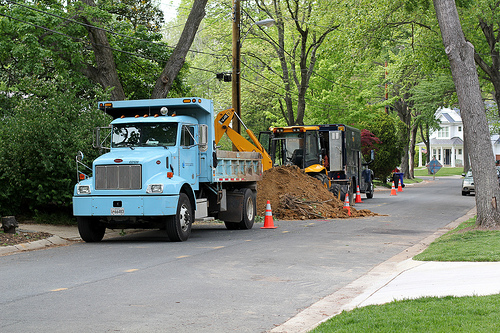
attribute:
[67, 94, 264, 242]
dump truck — blue, white, light blue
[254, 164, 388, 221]
dirt — piled, large, unloaded, red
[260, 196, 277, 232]
cone — orange, white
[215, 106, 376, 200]
road machine — orange, yellow, black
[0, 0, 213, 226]
trees — large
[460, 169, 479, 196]
car — parked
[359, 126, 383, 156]
tree — red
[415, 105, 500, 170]
house — large, white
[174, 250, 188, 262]
lines — yellow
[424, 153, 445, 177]
sign — at intersection, small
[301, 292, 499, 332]
grass — green, on sidewalk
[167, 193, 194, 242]
tire — black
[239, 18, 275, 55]
street lamp — white